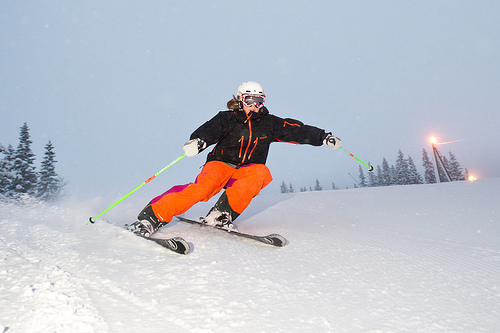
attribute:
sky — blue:
[2, 0, 498, 222]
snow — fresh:
[1, 171, 484, 331]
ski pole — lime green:
[83, 151, 183, 225]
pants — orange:
[136, 160, 272, 225]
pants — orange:
[136, 159, 273, 231]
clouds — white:
[59, 30, 146, 111]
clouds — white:
[404, 30, 446, 63]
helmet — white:
[232, 74, 279, 108]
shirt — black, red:
[183, 99, 314, 202]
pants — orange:
[176, 152, 283, 242]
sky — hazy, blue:
[311, 11, 496, 135]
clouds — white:
[59, 35, 138, 97]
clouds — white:
[311, 39, 387, 99]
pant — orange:
[216, 55, 275, 135]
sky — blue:
[23, 11, 94, 76]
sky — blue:
[78, 84, 173, 139]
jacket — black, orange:
[184, 110, 333, 169]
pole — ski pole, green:
[89, 148, 193, 226]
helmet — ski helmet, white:
[233, 80, 268, 107]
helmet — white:
[235, 79, 269, 98]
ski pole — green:
[89, 155, 182, 221]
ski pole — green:
[335, 137, 375, 177]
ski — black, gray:
[111, 216, 199, 254]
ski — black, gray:
[177, 208, 291, 254]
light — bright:
[426, 134, 441, 146]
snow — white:
[15, 187, 494, 330]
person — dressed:
[122, 81, 337, 240]